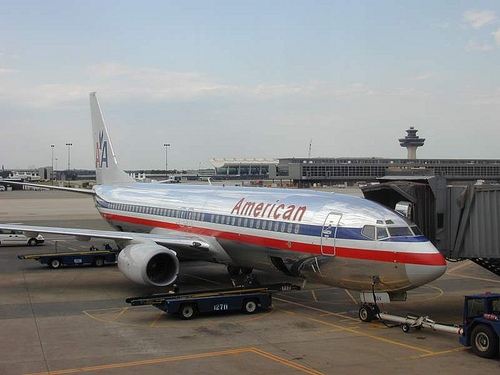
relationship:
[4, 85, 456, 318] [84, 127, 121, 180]
plane of american airlines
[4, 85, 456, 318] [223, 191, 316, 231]
plane has word american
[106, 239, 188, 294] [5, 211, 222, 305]
engine on right side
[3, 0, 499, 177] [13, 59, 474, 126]
sky with white clouds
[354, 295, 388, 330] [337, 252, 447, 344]
wheels on front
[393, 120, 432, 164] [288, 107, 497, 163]
signal tower in distance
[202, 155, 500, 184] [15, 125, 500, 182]
airport terminal on background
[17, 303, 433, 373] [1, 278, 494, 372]
lines on pavement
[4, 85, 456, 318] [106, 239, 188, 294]
plane has jet engine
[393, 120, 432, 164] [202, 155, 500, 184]
control tower on airport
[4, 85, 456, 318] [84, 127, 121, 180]
airplane of american airlines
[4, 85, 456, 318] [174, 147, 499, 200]
plane at terminal gate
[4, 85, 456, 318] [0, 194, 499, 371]
airplane parked at airport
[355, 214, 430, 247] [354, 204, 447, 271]
windows of cockpit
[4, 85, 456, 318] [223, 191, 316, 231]
plane written american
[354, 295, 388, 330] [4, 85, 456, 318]
wheel of plane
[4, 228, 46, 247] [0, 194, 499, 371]
car on airport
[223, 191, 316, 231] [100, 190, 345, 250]
word american side of plane.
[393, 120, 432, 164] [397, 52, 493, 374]
control tower on right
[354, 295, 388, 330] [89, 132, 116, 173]
wheels on american airline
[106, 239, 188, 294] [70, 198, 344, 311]
engine on left side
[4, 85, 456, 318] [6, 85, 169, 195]
plane has tail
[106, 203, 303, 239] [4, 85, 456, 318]
windows on side plane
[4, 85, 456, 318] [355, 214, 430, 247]
airplane has front windshields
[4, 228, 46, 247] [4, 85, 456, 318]
car on left of airplane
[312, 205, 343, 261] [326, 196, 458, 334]
door on front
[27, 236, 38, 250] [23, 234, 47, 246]
wheel of front side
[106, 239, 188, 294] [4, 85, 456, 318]
engine of plane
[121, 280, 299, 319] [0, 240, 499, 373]
cart on pavement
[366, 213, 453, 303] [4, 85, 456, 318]
nose on plane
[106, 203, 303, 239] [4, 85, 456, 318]
windows on plane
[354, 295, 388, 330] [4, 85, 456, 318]
wheel on plane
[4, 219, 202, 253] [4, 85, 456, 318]
wing on plane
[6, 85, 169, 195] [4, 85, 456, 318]
tail of plane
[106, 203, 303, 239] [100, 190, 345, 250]
windows of side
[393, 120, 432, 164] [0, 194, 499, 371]
control tower of airport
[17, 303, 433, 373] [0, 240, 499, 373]
lines of pavement